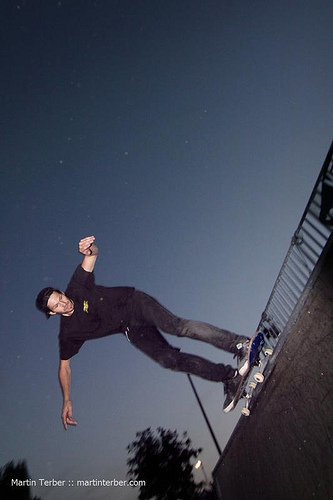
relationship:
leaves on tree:
[155, 453, 173, 481] [120, 422, 214, 494]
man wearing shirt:
[14, 225, 275, 434] [50, 263, 134, 360]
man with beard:
[35, 234, 255, 431] [59, 298, 75, 314]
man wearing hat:
[35, 234, 255, 431] [35, 286, 52, 319]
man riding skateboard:
[35, 234, 255, 431] [221, 332, 273, 415]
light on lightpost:
[192, 458, 203, 470] [191, 455, 215, 495]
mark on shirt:
[81, 300, 88, 313] [50, 263, 134, 360]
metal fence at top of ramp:
[267, 160, 316, 251] [209, 242, 321, 475]